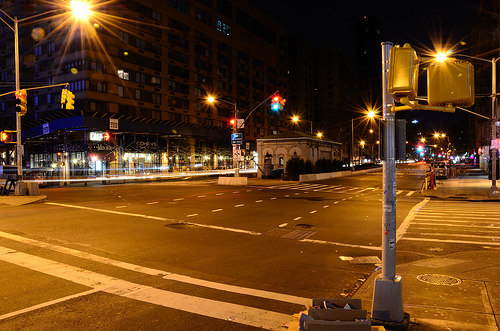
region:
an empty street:
[2, 4, 490, 329]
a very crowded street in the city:
[6, 4, 468, 328]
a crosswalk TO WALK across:
[20, 183, 305, 321]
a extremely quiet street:
[16, 25, 441, 306]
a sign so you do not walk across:
[0, 124, 40, 154]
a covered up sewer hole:
[415, 258, 499, 322]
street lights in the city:
[35, 2, 170, 92]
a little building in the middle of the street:
[203, 116, 357, 203]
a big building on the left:
[55, 6, 249, 160]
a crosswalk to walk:
[411, 151, 480, 271]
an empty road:
[102, 210, 297, 307]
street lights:
[195, 56, 303, 177]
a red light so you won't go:
[15, 82, 51, 161]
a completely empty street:
[28, 61, 445, 298]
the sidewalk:
[438, 270, 493, 329]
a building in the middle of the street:
[256, 128, 336, 202]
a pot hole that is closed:
[418, 261, 478, 303]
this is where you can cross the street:
[429, 186, 484, 263]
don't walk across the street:
[2, 122, 21, 150]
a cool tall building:
[78, 0, 174, 170]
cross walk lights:
[348, 25, 495, 325]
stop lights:
[138, 49, 340, 187]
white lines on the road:
[14, 162, 459, 312]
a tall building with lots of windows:
[51, 0, 380, 157]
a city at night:
[20, 13, 496, 272]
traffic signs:
[199, 117, 301, 203]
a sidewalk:
[384, 109, 499, 324]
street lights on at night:
[185, 62, 374, 215]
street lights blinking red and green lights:
[186, 74, 368, 194]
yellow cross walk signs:
[359, 7, 499, 215]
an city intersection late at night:
[7, 5, 499, 324]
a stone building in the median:
[242, 127, 347, 185]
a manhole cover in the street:
[415, 268, 462, 290]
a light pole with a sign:
[197, 85, 247, 180]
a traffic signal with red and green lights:
[230, 87, 285, 182]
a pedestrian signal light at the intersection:
[0, 125, 22, 147]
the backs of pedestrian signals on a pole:
[377, 40, 474, 125]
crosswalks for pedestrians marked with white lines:
[135, 175, 495, 325]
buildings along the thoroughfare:
[35, 30, 317, 185]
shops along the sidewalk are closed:
[12, 133, 252, 185]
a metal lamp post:
[11, 0, 102, 193]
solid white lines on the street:
[0, 227, 322, 329]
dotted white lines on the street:
[115, 181, 367, 228]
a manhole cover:
[415, 270, 463, 285]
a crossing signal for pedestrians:
[387, 44, 474, 116]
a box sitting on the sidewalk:
[287, 296, 380, 329]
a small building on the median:
[256, 125, 341, 175]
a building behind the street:
[22, 0, 311, 172]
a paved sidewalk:
[343, 249, 498, 329]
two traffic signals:
[228, 93, 279, 137]